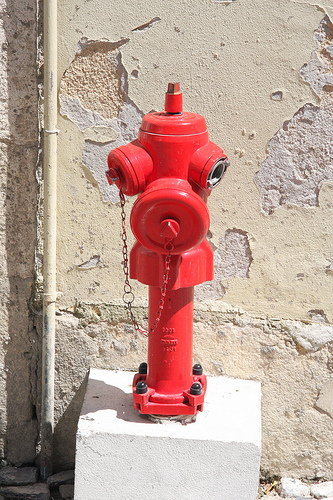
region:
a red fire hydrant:
[88, 89, 323, 304]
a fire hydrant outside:
[77, 121, 275, 374]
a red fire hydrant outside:
[59, 98, 233, 397]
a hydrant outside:
[44, 111, 265, 378]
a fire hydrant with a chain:
[85, 146, 228, 440]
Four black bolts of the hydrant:
[135, 359, 211, 408]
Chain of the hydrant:
[105, 175, 180, 347]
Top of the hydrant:
[152, 72, 190, 117]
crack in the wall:
[62, 28, 132, 124]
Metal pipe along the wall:
[33, 178, 60, 454]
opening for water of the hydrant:
[107, 141, 229, 249]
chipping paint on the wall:
[262, 53, 323, 155]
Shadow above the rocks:
[23, 427, 75, 499]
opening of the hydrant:
[184, 146, 243, 185]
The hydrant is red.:
[107, 82, 215, 424]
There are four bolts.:
[127, 356, 220, 410]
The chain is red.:
[102, 170, 182, 342]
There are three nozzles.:
[100, 131, 237, 247]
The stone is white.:
[82, 358, 268, 495]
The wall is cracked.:
[4, 5, 320, 366]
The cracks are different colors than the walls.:
[249, 100, 325, 225]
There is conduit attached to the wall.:
[43, 2, 63, 479]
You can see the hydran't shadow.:
[41, 378, 139, 472]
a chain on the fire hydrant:
[110, 195, 185, 334]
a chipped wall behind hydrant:
[8, 23, 331, 376]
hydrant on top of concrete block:
[88, 69, 236, 417]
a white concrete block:
[53, 364, 286, 498]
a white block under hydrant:
[51, 353, 305, 499]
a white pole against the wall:
[31, 2, 71, 450]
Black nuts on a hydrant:
[136, 356, 214, 405]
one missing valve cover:
[205, 148, 234, 198]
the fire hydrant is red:
[103, 81, 226, 421]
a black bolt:
[135, 380, 148, 395]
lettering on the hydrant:
[159, 325, 177, 353]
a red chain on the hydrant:
[117, 189, 173, 334]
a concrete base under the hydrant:
[73, 367, 261, 498]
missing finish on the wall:
[77, 256, 101, 268]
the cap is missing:
[203, 156, 231, 191]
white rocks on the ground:
[279, 477, 332, 498]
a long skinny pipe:
[41, 2, 55, 446]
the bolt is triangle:
[159, 222, 177, 237]